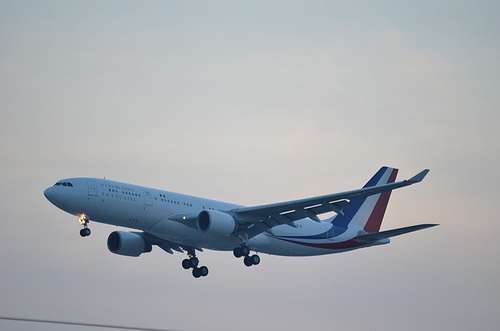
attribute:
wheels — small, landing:
[76, 223, 93, 240]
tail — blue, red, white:
[328, 166, 402, 232]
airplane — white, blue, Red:
[27, 150, 447, 277]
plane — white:
[40, 161, 442, 278]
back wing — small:
[363, 217, 438, 242]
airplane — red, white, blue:
[40, 161, 442, 282]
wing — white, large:
[235, 165, 432, 221]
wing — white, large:
[123, 225, 159, 249]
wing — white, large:
[361, 221, 437, 242]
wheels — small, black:
[73, 220, 103, 245]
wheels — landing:
[233, 244, 259, 266]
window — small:
[55, 181, 74, 186]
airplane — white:
[24, 133, 449, 294]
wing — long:
[235, 163, 431, 227]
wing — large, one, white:
[238, 167, 436, 224]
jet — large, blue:
[42, 166, 441, 278]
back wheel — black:
[239, 258, 267, 268]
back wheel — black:
[231, 245, 251, 258]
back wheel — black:
[187, 263, 211, 281]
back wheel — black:
[180, 253, 197, 269]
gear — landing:
[69, 212, 281, 282]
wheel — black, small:
[79, 227, 92, 240]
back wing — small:
[369, 225, 438, 239]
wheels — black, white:
[177, 240, 272, 282]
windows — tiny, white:
[115, 186, 239, 221]